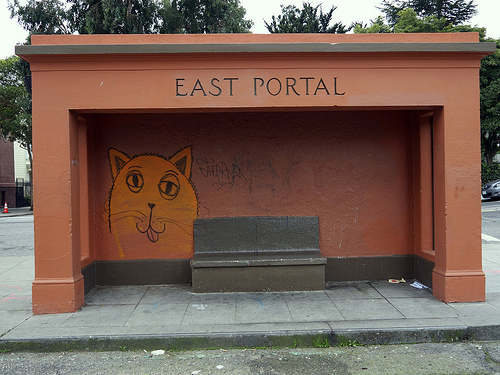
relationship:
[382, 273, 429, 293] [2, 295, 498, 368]
litter on floor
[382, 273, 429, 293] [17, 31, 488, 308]
litter at bus stop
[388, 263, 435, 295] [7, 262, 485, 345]
trash on ground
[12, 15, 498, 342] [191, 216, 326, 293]
stop over bench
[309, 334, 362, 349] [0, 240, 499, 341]
weeds on sidewalk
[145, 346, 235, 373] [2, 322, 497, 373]
trash in street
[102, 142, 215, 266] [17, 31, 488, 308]
cat on bus stop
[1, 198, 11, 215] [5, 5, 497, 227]
cone in background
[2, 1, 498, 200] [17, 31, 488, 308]
trees above bus stop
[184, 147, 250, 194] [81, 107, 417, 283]
graffiti in back wall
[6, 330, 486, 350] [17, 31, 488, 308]
curb in front of bus stop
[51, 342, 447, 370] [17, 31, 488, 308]
road in front of bus stop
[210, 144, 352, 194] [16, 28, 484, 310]
graffiti on portal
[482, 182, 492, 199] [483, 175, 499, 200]
nose of car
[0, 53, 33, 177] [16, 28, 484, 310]
tree behind portal